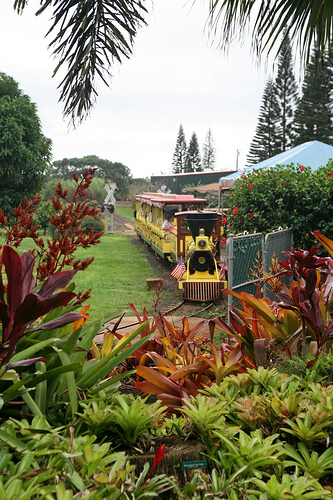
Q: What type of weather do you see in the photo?
A: It is overcast.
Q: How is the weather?
A: It is overcast.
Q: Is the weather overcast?
A: Yes, it is overcast.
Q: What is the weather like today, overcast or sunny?
A: It is overcast.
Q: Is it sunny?
A: No, it is overcast.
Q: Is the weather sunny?
A: No, it is overcast.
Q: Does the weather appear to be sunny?
A: No, it is overcast.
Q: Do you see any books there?
A: No, there are no books.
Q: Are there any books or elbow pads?
A: No, there are no books or elbow pads.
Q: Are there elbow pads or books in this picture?
A: No, there are no books or elbow pads.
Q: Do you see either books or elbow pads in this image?
A: No, there are no books or elbow pads.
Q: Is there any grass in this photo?
A: Yes, there is grass.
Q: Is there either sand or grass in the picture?
A: Yes, there is grass.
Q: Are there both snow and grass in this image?
A: No, there is grass but no snow.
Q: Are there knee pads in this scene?
A: No, there are no knee pads.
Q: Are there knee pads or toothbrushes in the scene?
A: No, there are no knee pads or toothbrushes.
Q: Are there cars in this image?
A: No, there are no cars.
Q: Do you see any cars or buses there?
A: No, there are no cars or buses.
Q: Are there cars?
A: No, there are no cars.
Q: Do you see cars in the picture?
A: No, there are no cars.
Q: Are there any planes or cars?
A: No, there are no cars or planes.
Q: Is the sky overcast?
A: Yes, the sky is overcast.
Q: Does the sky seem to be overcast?
A: Yes, the sky is overcast.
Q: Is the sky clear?
A: No, the sky is overcast.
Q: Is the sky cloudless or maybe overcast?
A: The sky is overcast.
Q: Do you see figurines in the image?
A: No, there are no figurines.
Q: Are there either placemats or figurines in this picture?
A: No, there are no figurines or placemats.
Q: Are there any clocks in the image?
A: No, there are no clocks.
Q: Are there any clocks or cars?
A: No, there are no clocks or cars.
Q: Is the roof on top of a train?
A: Yes, the roof is on top of a train.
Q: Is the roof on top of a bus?
A: No, the roof is on top of a train.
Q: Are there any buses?
A: No, there are no buses.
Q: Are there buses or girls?
A: No, there are no buses or girls.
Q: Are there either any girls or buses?
A: No, there are no buses or girls.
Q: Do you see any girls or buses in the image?
A: No, there are no buses or girls.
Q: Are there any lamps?
A: No, there are no lamps.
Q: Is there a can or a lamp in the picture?
A: No, there are no lamps or cans.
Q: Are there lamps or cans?
A: No, there are no lamps or cans.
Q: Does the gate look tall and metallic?
A: Yes, the gate is tall and metallic.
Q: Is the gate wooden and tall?
A: No, the gate is tall but metallic.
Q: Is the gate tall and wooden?
A: No, the gate is tall but metallic.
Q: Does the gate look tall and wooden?
A: No, the gate is tall but metallic.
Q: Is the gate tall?
A: Yes, the gate is tall.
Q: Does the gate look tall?
A: Yes, the gate is tall.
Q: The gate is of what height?
A: The gate is tall.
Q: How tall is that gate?
A: The gate is tall.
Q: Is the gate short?
A: No, the gate is tall.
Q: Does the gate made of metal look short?
A: No, the gate is tall.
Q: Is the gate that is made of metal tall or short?
A: The gate is tall.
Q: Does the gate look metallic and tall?
A: Yes, the gate is metallic and tall.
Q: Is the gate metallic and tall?
A: Yes, the gate is metallic and tall.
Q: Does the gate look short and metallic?
A: No, the gate is metallic but tall.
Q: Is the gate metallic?
A: Yes, the gate is metallic.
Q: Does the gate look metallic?
A: Yes, the gate is metallic.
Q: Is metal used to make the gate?
A: Yes, the gate is made of metal.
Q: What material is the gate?
A: The gate is made of metal.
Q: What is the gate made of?
A: The gate is made of metal.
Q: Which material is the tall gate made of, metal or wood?
A: The gate is made of metal.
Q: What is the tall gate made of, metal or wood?
A: The gate is made of metal.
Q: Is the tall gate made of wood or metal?
A: The gate is made of metal.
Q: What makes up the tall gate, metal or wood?
A: The gate is made of metal.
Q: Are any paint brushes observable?
A: No, there are no paint brushes.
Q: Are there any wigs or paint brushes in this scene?
A: No, there are no paint brushes or wigs.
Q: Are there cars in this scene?
A: No, there are no cars.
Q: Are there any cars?
A: No, there are no cars.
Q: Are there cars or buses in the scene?
A: No, there are no cars or buses.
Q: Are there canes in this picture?
A: No, there are no canes.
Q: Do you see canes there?
A: No, there are no canes.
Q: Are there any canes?
A: No, there are no canes.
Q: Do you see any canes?
A: No, there are no canes.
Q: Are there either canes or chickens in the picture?
A: No, there are no canes or chickens.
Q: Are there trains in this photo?
A: Yes, there is a train.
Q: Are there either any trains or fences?
A: Yes, there is a train.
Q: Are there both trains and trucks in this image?
A: No, there is a train but no trucks.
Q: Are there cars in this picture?
A: No, there are no cars.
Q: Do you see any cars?
A: No, there are no cars.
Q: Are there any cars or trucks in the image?
A: No, there are no cars or trucks.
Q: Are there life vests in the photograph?
A: No, there are no life vests.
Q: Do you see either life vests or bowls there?
A: No, there are no life vests or bowls.